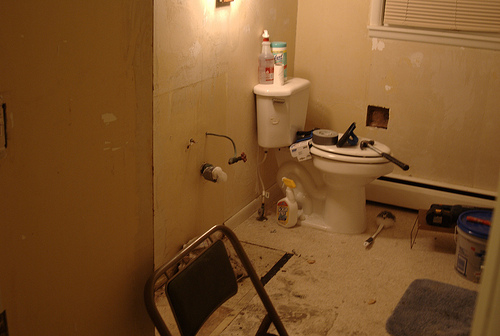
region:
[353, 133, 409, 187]
the hammer on the toilet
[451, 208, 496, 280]
the gray bucket on the floor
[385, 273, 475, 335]
the rug beside the bucket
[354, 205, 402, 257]
the toilet brush on the floor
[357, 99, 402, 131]
the small hole in the wall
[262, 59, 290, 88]
the roll of toilet paper on the toilet tank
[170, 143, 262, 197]
the plumbing on the wall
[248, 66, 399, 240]
the toilet is white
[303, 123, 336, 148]
the roll of duct tape on the toilet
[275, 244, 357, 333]
the floor is dirty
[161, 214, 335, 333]
Bathroom floor is very dirty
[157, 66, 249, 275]
The sink is missing from the bathroom wall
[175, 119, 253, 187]
Bare pipes and a drain juts from the wall.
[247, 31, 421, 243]
Toilet is covered in tools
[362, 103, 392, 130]
Toilet paper holder is missing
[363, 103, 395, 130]
A hole is in the wall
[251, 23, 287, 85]
Cleaning supplies sit on the top of the toilet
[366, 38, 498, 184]
The wall has damaged paint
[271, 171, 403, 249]
Cleaning supplies laying on the floor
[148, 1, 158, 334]
Wall corner at room entrance is damaged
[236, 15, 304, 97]
cleaning products in a bathroom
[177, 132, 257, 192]
the water knobs in the bathroom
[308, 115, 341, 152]
duct tape on the toilet seat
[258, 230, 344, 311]
a floor being torn up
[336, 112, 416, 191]
a tool for remodeling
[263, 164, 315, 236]
a bottle of cleaning stuff in the floor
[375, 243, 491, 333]
a rug in the bathroom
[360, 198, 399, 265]
a toilet bowl cleaner brush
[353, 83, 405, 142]
a hole in the bathroom wall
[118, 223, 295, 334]
a stool for the workers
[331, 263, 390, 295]
this is the floor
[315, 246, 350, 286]
the floor is white in color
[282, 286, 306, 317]
the floor is dirty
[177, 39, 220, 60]
this is the wall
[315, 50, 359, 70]
the wall is white in color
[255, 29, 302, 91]
these are some containers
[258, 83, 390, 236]
this is a toilet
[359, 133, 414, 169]
this is a hammer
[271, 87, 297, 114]
the toilet is white in color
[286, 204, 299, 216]
the container is white in color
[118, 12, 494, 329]
Bathroom under going renovation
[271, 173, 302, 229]
Toilet cleaning sitting on floor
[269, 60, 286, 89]
Partial roll of toilet paper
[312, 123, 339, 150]
Grey masking tape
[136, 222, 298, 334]
Grey metal step stool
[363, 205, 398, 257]
Toilet scrub brush on floor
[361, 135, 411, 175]
Black and silver hammer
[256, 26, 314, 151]
Products sitting on toilet tank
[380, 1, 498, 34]
Closed plastic window blinds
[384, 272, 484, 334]
Blue dirty bathroom rug